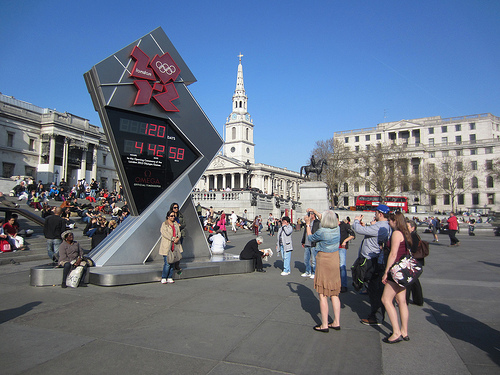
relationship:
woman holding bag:
[376, 208, 424, 348] [387, 232, 427, 294]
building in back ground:
[330, 116, 499, 221] [21, 113, 454, 188]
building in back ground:
[184, 44, 308, 231] [21, 113, 454, 188]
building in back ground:
[3, 93, 120, 195] [21, 113, 454, 188]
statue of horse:
[301, 157, 326, 180] [299, 157, 330, 182]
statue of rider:
[301, 157, 326, 180] [307, 155, 321, 173]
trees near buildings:
[301, 135, 463, 215] [0, 42, 498, 232]